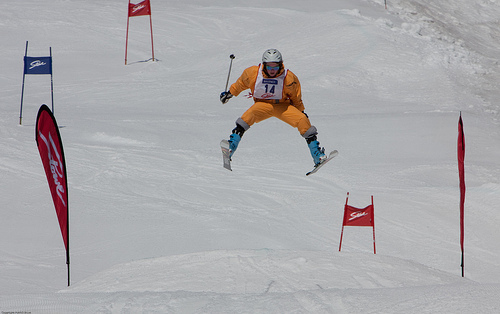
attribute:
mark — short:
[336, 188, 379, 257]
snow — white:
[1, 0, 497, 312]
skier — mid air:
[215, 43, 339, 183]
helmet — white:
[260, 46, 282, 63]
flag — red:
[336, 189, 381, 231]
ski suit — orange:
[239, 72, 301, 122]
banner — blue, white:
[16, 37, 56, 72]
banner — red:
[334, 188, 382, 256]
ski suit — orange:
[228, 60, 314, 140]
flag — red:
[338, 190, 380, 247]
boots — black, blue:
[305, 128, 332, 170]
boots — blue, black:
[228, 116, 244, 167]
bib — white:
[252, 69, 279, 104]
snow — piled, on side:
[384, 9, 499, 76]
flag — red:
[342, 198, 375, 228]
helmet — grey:
[260, 47, 283, 81]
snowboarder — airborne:
[212, 48, 329, 168]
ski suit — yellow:
[229, 64, 316, 144]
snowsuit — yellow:
[222, 68, 316, 138]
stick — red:
[364, 188, 382, 255]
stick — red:
[337, 188, 347, 249]